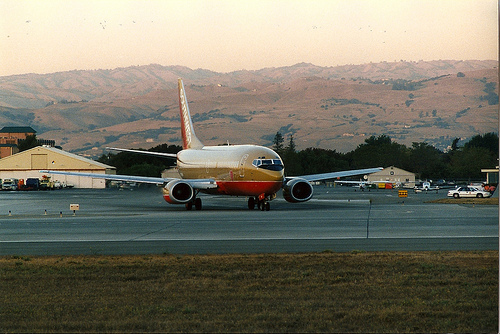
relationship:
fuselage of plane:
[177, 140, 284, 196] [59, 98, 314, 205]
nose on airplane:
[258, 168, 287, 185] [39, 77, 384, 211]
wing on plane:
[282, 157, 399, 183] [86, 103, 406, 211]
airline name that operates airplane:
[178, 86, 191, 143] [39, 77, 384, 211]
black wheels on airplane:
[184, 198, 206, 208] [39, 77, 384, 211]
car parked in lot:
[448, 182, 491, 200] [350, 184, 484, 198]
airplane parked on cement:
[39, 77, 384, 211] [0, 188, 499, 256]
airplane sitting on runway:
[39, 77, 384, 211] [6, 212, 481, 245]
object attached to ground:
[4, 210, 12, 216] [7, 170, 495, 326]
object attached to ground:
[41, 208, 51, 215] [7, 170, 495, 326]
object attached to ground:
[56, 205, 66, 218] [7, 170, 495, 326]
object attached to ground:
[71, 207, 77, 216] [7, 170, 495, 326]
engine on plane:
[157, 178, 198, 207] [49, 54, 414, 276]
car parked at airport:
[447, 185, 492, 199] [6, 68, 496, 259]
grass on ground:
[306, 254, 426, 332] [3, 180, 493, 331]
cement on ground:
[0, 188, 499, 256] [3, 180, 493, 331]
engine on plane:
[283, 177, 315, 203] [33, 142, 388, 204]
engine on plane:
[163, 179, 195, 204] [64, 62, 387, 212]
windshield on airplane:
[247, 157, 286, 167] [39, 77, 384, 211]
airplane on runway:
[39, 77, 384, 211] [2, 188, 499, 245]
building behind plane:
[2, 147, 116, 189] [38, 102, 384, 207]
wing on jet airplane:
[40, 158, 224, 192] [47, 79, 388, 217]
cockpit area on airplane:
[256, 155, 286, 168] [39, 77, 384, 211]